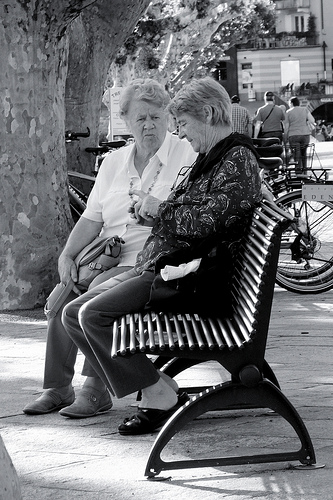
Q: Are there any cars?
A: No, there are no cars.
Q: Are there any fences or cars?
A: No, there are no cars or fences.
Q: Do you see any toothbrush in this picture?
A: No, there are no toothbrushes.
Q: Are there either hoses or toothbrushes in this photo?
A: No, there are no toothbrushes or hoses.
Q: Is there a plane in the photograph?
A: No, there are no airplanes.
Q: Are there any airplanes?
A: No, there are no airplanes.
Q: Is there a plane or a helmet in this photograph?
A: No, there are no airplanes or helmets.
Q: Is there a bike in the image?
A: Yes, there is a bike.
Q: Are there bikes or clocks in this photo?
A: Yes, there is a bike.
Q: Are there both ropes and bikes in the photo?
A: No, there is a bike but no ropes.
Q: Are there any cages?
A: No, there are no cages.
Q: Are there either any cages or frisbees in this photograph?
A: No, there are no cages or frisbees.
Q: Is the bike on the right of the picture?
A: Yes, the bike is on the right of the image.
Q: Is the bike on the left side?
A: No, the bike is on the right of the image.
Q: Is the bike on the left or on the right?
A: The bike is on the right of the image.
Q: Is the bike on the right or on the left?
A: The bike is on the right of the image.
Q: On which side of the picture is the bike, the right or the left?
A: The bike is on the right of the image.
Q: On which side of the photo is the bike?
A: The bike is on the right of the image.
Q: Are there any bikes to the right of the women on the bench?
A: Yes, there is a bike to the right of the women.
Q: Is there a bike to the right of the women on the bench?
A: Yes, there is a bike to the right of the women.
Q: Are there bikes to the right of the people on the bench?
A: Yes, there is a bike to the right of the women.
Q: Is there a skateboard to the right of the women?
A: No, there is a bike to the right of the women.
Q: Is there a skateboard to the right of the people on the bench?
A: No, there is a bike to the right of the women.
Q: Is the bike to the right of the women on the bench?
A: Yes, the bike is to the right of the women.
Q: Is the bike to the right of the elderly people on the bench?
A: Yes, the bike is to the right of the women.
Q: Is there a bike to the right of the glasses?
A: Yes, there is a bike to the right of the glasses.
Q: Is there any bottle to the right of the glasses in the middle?
A: No, there is a bike to the right of the glasses.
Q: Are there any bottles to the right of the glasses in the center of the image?
A: No, there is a bike to the right of the glasses.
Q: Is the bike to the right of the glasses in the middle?
A: Yes, the bike is to the right of the glasses.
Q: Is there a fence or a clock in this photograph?
A: No, there are no fences or clocks.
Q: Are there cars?
A: No, there are no cars.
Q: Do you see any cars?
A: No, there are no cars.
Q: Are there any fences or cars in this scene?
A: No, there are no cars or fences.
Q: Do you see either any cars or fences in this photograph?
A: No, there are no cars or fences.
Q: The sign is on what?
A: The sign is on the bike.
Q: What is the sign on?
A: The sign is on the bike.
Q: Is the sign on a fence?
A: No, the sign is on the bike.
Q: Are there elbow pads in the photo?
A: No, there are no elbow pads.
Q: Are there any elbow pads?
A: No, there are no elbow pads.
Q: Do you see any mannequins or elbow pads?
A: No, there are no elbow pads or mannequins.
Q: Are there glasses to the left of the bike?
A: Yes, there are glasses to the left of the bike.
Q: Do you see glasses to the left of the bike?
A: Yes, there are glasses to the left of the bike.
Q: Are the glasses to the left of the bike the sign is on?
A: Yes, the glasses are to the left of the bike.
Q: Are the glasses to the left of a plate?
A: No, the glasses are to the left of the bike.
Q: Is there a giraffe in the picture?
A: No, there are no giraffes.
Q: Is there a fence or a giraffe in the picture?
A: No, there are no giraffes or fences.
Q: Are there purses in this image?
A: Yes, there is a purse.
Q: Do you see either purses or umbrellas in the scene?
A: Yes, there is a purse.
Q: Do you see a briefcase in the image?
A: No, there are no briefcases.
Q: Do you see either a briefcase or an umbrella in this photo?
A: No, there are no briefcases or umbrellas.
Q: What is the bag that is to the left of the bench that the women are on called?
A: The bag is a purse.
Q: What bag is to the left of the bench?
A: The bag is a purse.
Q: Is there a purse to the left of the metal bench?
A: Yes, there is a purse to the left of the bench.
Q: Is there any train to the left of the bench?
A: No, there is a purse to the left of the bench.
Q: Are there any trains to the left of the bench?
A: No, there is a purse to the left of the bench.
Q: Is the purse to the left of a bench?
A: Yes, the purse is to the left of a bench.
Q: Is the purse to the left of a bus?
A: No, the purse is to the left of a bench.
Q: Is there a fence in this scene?
A: No, there are no fences.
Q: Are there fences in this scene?
A: No, there are no fences.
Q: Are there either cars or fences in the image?
A: No, there are no fences or cars.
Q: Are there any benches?
A: Yes, there is a bench.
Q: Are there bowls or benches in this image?
A: Yes, there is a bench.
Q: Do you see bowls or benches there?
A: Yes, there is a bench.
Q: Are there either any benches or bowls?
A: Yes, there is a bench.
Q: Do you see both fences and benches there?
A: No, there is a bench but no fences.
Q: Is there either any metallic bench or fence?
A: Yes, there is a metal bench.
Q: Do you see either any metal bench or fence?
A: Yes, there is a metal bench.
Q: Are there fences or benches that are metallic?
A: Yes, the bench is metallic.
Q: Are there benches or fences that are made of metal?
A: Yes, the bench is made of metal.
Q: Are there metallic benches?
A: Yes, there is a metal bench.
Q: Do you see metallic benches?
A: Yes, there is a metal bench.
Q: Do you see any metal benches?
A: Yes, there is a metal bench.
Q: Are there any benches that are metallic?
A: Yes, there is a bench that is metallic.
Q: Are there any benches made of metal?
A: Yes, there is a bench that is made of metal.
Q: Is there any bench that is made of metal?
A: Yes, there is a bench that is made of metal.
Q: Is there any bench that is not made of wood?
A: Yes, there is a bench that is made of metal.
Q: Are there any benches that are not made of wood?
A: Yes, there is a bench that is made of metal.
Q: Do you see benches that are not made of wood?
A: Yes, there is a bench that is made of metal.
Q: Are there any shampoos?
A: No, there are no shampoos.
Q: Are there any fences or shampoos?
A: No, there are no shampoos or fences.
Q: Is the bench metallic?
A: Yes, the bench is metallic.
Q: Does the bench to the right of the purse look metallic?
A: Yes, the bench is metallic.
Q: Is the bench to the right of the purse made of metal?
A: Yes, the bench is made of metal.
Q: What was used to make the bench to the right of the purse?
A: The bench is made of metal.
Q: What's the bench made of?
A: The bench is made of metal.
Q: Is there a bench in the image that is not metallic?
A: No, there is a bench but it is metallic.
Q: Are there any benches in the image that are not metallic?
A: No, there is a bench but it is metallic.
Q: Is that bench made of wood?
A: No, the bench is made of metal.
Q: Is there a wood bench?
A: No, there is a bench but it is made of metal.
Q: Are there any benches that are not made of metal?
A: No, there is a bench but it is made of metal.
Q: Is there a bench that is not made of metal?
A: No, there is a bench but it is made of metal.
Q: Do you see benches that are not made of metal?
A: No, there is a bench but it is made of metal.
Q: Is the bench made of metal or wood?
A: The bench is made of metal.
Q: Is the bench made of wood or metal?
A: The bench is made of metal.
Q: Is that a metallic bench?
A: Yes, that is a metallic bench.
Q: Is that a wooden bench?
A: No, that is a metallic bench.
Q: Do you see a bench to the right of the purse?
A: Yes, there is a bench to the right of the purse.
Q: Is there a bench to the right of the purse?
A: Yes, there is a bench to the right of the purse.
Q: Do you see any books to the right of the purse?
A: No, there is a bench to the right of the purse.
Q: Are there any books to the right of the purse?
A: No, there is a bench to the right of the purse.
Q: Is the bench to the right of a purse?
A: Yes, the bench is to the right of a purse.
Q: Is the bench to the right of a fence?
A: No, the bench is to the right of a purse.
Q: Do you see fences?
A: No, there are no fences.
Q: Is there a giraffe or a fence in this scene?
A: No, there are no fences or giraffes.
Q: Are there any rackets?
A: No, there are no rackets.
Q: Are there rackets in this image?
A: No, there are no rackets.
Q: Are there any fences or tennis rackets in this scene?
A: No, there are no tennis rackets or fences.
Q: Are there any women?
A: Yes, there are women.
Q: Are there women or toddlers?
A: Yes, there are women.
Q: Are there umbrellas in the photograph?
A: No, there are no umbrellas.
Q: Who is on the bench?
A: The women are on the bench.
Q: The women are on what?
A: The women are on the bench.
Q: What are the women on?
A: The women are on the bench.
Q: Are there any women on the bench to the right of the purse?
A: Yes, there are women on the bench.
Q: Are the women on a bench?
A: Yes, the women are on a bench.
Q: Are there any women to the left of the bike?
A: Yes, there are women to the left of the bike.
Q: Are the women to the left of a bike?
A: Yes, the women are to the left of a bike.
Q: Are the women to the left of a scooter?
A: No, the women are to the left of a bike.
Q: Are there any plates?
A: No, there are no plates.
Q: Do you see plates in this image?
A: No, there are no plates.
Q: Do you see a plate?
A: No, there are no plates.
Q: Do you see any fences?
A: No, there are no fences.